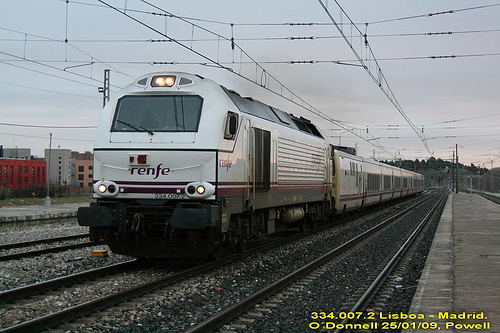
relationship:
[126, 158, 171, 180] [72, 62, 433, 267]
label on train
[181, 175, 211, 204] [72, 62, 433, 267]
headlights on train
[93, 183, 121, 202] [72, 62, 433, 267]
headlights on train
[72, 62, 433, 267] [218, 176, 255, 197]
train has stripes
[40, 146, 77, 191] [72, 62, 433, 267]
building near train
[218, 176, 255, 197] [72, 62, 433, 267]
stripes on train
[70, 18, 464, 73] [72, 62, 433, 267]
wires above train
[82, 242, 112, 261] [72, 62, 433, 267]
object next to train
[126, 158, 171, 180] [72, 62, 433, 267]
label on front of train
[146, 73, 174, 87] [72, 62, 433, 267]
headlights on train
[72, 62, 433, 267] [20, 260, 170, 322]
train on tracks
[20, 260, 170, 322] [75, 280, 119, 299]
tracks has gravel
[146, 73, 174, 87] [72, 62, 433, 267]
headlights on front of train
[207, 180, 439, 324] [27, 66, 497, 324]
rails in station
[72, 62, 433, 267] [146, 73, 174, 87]
train has headlights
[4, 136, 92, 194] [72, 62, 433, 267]
buildings near train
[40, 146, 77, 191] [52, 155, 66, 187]
building has windows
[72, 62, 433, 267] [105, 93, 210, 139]
train has windsheild